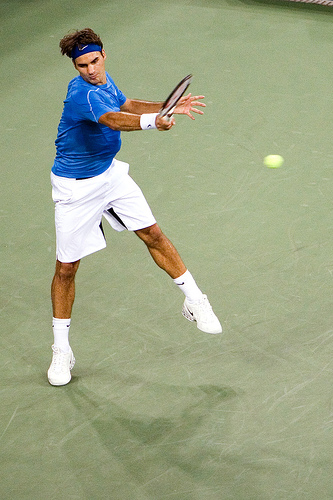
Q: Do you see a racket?
A: Yes, there is a racket.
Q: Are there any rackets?
A: Yes, there is a racket.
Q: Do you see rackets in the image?
A: Yes, there is a racket.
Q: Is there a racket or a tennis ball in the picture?
A: Yes, there is a racket.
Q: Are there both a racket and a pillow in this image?
A: No, there is a racket but no pillows.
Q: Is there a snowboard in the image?
A: No, there are no snowboards.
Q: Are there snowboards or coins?
A: No, there are no snowboards or coins.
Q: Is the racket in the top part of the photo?
A: Yes, the racket is in the top of the image.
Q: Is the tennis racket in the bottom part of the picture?
A: No, the tennis racket is in the top of the image.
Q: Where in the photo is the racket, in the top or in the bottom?
A: The racket is in the top of the image.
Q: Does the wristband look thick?
A: Yes, the wristband is thick.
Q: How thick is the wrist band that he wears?
A: The wristband is thick.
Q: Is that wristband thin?
A: No, the wristband is thick.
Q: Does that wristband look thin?
A: No, the wristband is thick.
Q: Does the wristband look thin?
A: No, the wristband is thick.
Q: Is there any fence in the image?
A: No, there are no fences.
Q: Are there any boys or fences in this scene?
A: No, there are no boys or fences.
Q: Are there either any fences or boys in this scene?
A: No, there are no boys or fences.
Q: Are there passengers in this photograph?
A: No, there are no passengers.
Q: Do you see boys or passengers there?
A: No, there are no passengers or boys.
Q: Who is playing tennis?
A: The man is playing tennis.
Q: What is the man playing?
A: The man is playing tennis.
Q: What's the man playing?
A: The man is playing tennis.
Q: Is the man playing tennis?
A: Yes, the man is playing tennis.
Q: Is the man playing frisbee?
A: No, the man is playing tennis.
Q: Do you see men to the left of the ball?
A: Yes, there is a man to the left of the ball.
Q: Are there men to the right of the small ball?
A: No, the man is to the left of the ball.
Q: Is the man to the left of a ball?
A: Yes, the man is to the left of a ball.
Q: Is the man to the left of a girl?
A: No, the man is to the left of a ball.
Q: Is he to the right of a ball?
A: No, the man is to the left of a ball.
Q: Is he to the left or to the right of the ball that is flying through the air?
A: The man is to the left of the ball.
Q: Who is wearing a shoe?
A: The man is wearing a shoe.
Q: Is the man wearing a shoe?
A: Yes, the man is wearing a shoe.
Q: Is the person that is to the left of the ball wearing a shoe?
A: Yes, the man is wearing a shoe.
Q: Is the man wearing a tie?
A: No, the man is wearing a shoe.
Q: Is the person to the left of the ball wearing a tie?
A: No, the man is wearing a shoe.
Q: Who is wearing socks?
A: The man is wearing socks.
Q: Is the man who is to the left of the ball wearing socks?
A: Yes, the man is wearing socks.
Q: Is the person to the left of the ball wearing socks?
A: Yes, the man is wearing socks.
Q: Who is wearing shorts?
A: The man is wearing shorts.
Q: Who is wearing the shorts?
A: The man is wearing shorts.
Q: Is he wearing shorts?
A: Yes, the man is wearing shorts.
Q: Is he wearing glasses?
A: No, the man is wearing shorts.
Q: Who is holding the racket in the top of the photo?
A: The man is holding the tennis racket.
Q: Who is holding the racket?
A: The man is holding the tennis racket.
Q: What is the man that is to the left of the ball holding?
A: The man is holding the racket.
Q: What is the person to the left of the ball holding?
A: The man is holding the racket.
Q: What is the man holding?
A: The man is holding the racket.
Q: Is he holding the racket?
A: Yes, the man is holding the racket.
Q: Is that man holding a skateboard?
A: No, the man is holding the racket.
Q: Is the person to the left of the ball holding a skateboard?
A: No, the man is holding the racket.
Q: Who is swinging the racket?
A: The man is swinging the racket.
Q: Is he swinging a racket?
A: Yes, the man is swinging a racket.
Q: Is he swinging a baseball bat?
A: No, the man is swinging a racket.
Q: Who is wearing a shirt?
A: The man is wearing a shirt.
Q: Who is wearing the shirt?
A: The man is wearing a shirt.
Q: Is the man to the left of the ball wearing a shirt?
A: Yes, the man is wearing a shirt.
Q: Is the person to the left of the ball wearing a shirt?
A: Yes, the man is wearing a shirt.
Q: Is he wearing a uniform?
A: No, the man is wearing a shirt.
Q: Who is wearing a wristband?
A: The man is wearing a wristband.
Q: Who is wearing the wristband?
A: The man is wearing a wristband.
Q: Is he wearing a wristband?
A: Yes, the man is wearing a wristband.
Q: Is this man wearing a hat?
A: No, the man is wearing a wristband.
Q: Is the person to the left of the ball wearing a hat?
A: No, the man is wearing a wristband.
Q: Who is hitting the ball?
A: The man is hitting the ball.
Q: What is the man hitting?
A: The man is hitting the ball.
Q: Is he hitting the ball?
A: Yes, the man is hitting the ball.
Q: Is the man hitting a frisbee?
A: No, the man is hitting the ball.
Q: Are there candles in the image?
A: No, there are no candles.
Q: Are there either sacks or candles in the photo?
A: No, there are no candles or sacks.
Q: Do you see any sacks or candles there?
A: No, there are no candles or sacks.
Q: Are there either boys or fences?
A: No, there are no boys or fences.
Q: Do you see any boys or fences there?
A: No, there are no boys or fences.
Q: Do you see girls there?
A: No, there are no girls.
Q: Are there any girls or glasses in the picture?
A: No, there are no girls or glasses.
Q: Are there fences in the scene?
A: No, there are no fences.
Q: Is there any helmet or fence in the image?
A: No, there are no fences or helmets.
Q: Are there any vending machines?
A: No, there are no vending machines.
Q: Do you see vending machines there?
A: No, there are no vending machines.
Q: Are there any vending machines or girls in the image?
A: No, there are no vending machines or girls.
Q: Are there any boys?
A: No, there are no boys.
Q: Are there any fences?
A: No, there are no fences.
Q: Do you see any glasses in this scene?
A: No, there are no glasses.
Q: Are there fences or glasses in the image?
A: No, there are no glasses or fences.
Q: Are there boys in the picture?
A: No, there are no boys.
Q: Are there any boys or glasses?
A: No, there are no boys or glasses.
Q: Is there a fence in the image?
A: No, there are no fences.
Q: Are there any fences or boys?
A: No, there are no fences or boys.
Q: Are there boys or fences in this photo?
A: No, there are no fences or boys.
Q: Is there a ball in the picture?
A: Yes, there is a ball.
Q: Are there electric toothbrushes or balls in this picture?
A: Yes, there is a ball.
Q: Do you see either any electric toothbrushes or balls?
A: Yes, there is a ball.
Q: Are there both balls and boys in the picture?
A: No, there is a ball but no boys.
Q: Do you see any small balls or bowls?
A: Yes, there is a small ball.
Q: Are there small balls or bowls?
A: Yes, there is a small ball.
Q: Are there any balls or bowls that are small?
A: Yes, the ball is small.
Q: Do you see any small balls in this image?
A: Yes, there is a small ball.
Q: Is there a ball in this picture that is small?
A: Yes, there is a ball that is small.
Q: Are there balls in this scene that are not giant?
A: Yes, there is a small ball.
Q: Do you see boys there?
A: No, there are no boys.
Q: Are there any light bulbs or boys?
A: No, there are no boys or light bulbs.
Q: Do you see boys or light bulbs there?
A: No, there are no boys or light bulbs.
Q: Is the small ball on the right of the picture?
A: Yes, the ball is on the right of the image.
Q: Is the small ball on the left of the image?
A: No, the ball is on the right of the image.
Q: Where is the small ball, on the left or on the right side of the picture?
A: The ball is on the right of the image.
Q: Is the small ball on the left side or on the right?
A: The ball is on the right of the image.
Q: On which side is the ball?
A: The ball is on the right of the image.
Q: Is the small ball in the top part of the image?
A: Yes, the ball is in the top of the image.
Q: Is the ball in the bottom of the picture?
A: No, the ball is in the top of the image.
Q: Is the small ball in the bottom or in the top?
A: The ball is in the top of the image.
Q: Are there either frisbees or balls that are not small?
A: No, there is a ball but it is small.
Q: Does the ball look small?
A: Yes, the ball is small.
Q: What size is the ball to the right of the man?
A: The ball is small.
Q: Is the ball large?
A: No, the ball is small.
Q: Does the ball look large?
A: No, the ball is small.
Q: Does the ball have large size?
A: No, the ball is small.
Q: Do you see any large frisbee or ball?
A: No, there is a ball but it is small.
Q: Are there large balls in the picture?
A: No, there is a ball but it is small.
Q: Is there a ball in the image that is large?
A: No, there is a ball but it is small.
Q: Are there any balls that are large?
A: No, there is a ball but it is small.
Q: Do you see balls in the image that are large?
A: No, there is a ball but it is small.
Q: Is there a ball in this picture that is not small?
A: No, there is a ball but it is small.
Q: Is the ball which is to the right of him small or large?
A: The ball is small.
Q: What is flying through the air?
A: The ball is flying through the air.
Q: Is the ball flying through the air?
A: Yes, the ball is flying through the air.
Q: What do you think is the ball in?
A: The ball is in the air.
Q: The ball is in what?
A: The ball is in the air.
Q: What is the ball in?
A: The ball is in the air.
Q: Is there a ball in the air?
A: Yes, there is a ball in the air.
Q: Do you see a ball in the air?
A: Yes, there is a ball in the air.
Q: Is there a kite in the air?
A: No, there is a ball in the air.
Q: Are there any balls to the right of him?
A: Yes, there is a ball to the right of the man.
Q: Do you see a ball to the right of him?
A: Yes, there is a ball to the right of the man.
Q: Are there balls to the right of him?
A: Yes, there is a ball to the right of the man.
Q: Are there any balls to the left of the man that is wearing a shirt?
A: No, the ball is to the right of the man.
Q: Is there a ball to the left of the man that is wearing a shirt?
A: No, the ball is to the right of the man.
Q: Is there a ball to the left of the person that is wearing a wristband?
A: No, the ball is to the right of the man.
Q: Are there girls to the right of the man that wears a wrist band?
A: No, there is a ball to the right of the man.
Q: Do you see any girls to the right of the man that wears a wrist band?
A: No, there is a ball to the right of the man.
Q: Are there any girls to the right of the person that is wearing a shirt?
A: No, there is a ball to the right of the man.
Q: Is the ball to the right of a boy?
A: No, the ball is to the right of the man.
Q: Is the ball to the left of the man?
A: No, the ball is to the right of the man.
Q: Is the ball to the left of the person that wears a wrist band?
A: No, the ball is to the right of the man.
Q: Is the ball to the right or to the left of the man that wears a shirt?
A: The ball is to the right of the man.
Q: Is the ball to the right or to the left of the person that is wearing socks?
A: The ball is to the right of the man.